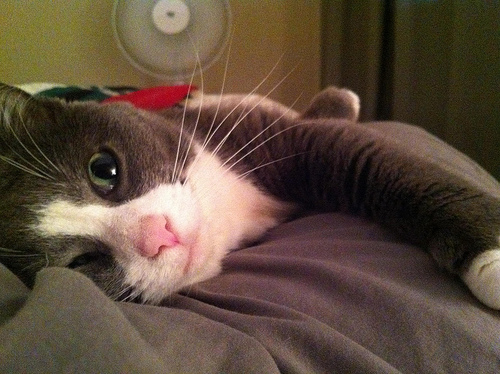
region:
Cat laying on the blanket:
[20, 73, 455, 360]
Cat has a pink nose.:
[102, 212, 192, 253]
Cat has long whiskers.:
[147, 100, 287, 176]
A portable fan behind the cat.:
[110, 2, 250, 80]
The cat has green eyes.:
[55, 122, 118, 273]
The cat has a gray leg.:
[288, 115, 449, 230]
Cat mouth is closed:
[187, 218, 213, 283]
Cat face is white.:
[112, 191, 230, 281]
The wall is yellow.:
[15, 15, 155, 76]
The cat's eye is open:
[56, 127, 128, 202]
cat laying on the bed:
[3, 46, 465, 333]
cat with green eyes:
[63, 143, 138, 208]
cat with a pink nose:
[133, 212, 175, 258]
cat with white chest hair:
[170, 155, 252, 235]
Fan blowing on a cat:
[108, 4, 233, 76]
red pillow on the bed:
[96, 75, 209, 116]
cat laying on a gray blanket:
[81, 284, 305, 371]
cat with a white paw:
[451, 234, 498, 287]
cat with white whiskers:
[153, 92, 250, 196]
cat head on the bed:
[26, 88, 212, 295]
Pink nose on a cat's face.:
[131, 214, 179, 257]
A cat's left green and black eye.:
[85, 150, 119, 195]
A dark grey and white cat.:
[1, 84, 498, 315]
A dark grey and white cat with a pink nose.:
[2, 81, 213, 301]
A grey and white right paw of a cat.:
[303, 85, 359, 125]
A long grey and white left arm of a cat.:
[286, 122, 498, 309]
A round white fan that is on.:
[110, 0, 234, 83]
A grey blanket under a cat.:
[1, 118, 498, 370]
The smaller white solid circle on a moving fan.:
[150, 1, 192, 33]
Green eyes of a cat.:
[65, 146, 120, 271]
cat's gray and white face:
[2, 80, 208, 289]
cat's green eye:
[89, 148, 124, 195]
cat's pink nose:
[140, 211, 180, 261]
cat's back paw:
[317, 84, 362, 117]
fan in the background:
[109, 0, 226, 77]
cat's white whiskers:
[174, 33, 308, 182]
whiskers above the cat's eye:
[3, 102, 73, 189]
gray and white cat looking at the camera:
[2, 77, 490, 322]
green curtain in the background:
[364, 3, 491, 120]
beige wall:
[0, 0, 102, 80]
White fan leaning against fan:
[113, 0, 234, 91]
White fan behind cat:
[112, 0, 233, 96]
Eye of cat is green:
[82, 144, 120, 195]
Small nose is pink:
[135, 210, 179, 257]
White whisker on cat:
[167, 43, 202, 180]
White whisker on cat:
[181, 15, 294, 182]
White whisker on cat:
[204, 148, 312, 218]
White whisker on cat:
[212, 85, 307, 189]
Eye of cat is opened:
[85, 141, 117, 191]